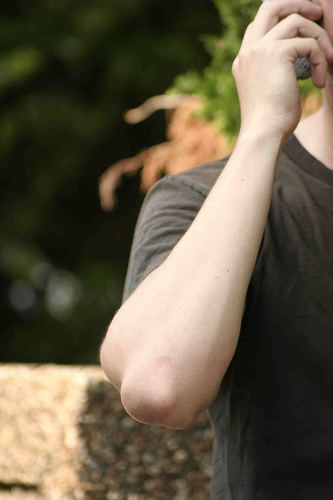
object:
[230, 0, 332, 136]
hand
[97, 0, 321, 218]
trees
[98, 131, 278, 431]
arm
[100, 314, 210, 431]
elbow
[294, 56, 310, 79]
cellphone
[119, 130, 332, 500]
shirt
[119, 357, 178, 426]
funny bone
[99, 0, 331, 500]
man